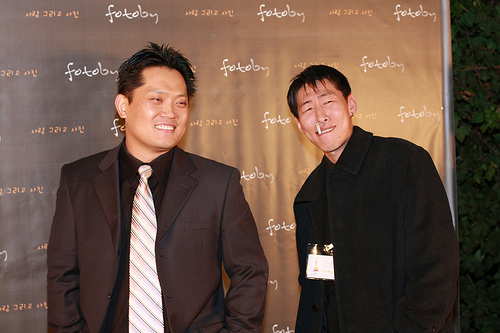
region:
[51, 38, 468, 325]
men standing side by side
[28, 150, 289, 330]
jacket on the man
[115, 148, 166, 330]
shirt on the man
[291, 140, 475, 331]
coat on the man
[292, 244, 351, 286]
card with clip on the man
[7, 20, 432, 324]
backdrop men stand against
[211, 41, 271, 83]
lettering on the backdrop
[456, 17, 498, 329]
leaves in the back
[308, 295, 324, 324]
button on the coat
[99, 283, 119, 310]
button on the jacket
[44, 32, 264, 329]
This is a person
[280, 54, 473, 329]
This is a person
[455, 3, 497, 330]
green tree leaves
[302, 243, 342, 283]
a name tag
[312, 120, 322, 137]
a white cigarette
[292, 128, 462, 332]
a man's black coat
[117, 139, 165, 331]
part of a man's black collared shirt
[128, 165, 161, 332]
a man's long striped tie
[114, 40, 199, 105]
a man's short cut black hair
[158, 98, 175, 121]
the nose of a man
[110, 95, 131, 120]
the ear of a man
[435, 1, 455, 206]
a long gray pole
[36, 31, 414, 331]
two men standing outside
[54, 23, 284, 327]
a man wearing tie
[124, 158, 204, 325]
white and silver tie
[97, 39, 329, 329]
a man wearing asuit jacket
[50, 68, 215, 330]
a man wearing a suit and tie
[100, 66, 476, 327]
the men are smiling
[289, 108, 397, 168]
the man has a cigarette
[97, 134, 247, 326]
the man has a striped tie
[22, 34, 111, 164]
writing is on the wall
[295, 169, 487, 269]
the man has a black jacket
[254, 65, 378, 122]
the man has dark hair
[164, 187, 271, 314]
the man is wearing a dark jacket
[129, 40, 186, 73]
the man has spiky hair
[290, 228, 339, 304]
the badge is white